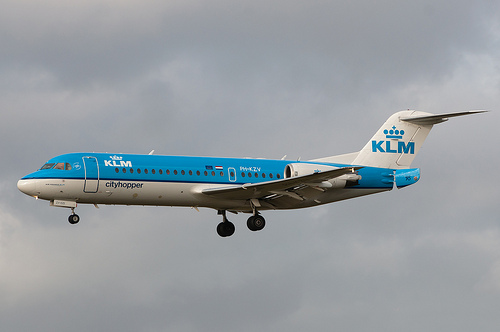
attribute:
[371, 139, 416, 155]
klm — blue, royal, cityhopper, logo, word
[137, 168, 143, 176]
windows — round, small, passanger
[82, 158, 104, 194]
door — tall, exit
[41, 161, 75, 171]
windscreen — wide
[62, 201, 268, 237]
gear — up, black, lowered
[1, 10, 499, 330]
sky — cloudy, grey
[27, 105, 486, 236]
airplane — flying, blue, white, klm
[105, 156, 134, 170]
lettering — white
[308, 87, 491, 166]
tail — white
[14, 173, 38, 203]
nose — white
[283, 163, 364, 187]
engine — white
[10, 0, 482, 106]
clouds — thick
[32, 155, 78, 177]
cabin — pilot cabin